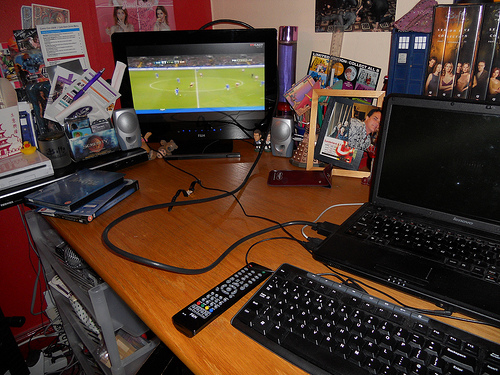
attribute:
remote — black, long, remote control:
[172, 262, 271, 338]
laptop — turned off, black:
[310, 93, 499, 324]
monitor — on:
[110, 26, 277, 145]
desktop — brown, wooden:
[39, 157, 230, 374]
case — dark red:
[267, 167, 333, 191]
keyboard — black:
[232, 263, 499, 375]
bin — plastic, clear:
[16, 214, 151, 374]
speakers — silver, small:
[270, 115, 294, 161]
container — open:
[1, 77, 23, 159]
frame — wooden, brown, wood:
[307, 84, 386, 176]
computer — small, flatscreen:
[112, 24, 277, 160]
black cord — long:
[101, 126, 336, 276]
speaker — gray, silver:
[112, 109, 143, 154]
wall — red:
[0, 1, 214, 29]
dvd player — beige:
[0, 152, 54, 191]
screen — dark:
[372, 98, 499, 226]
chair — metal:
[0, 309, 26, 374]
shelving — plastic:
[26, 216, 161, 374]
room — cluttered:
[0, 1, 499, 375]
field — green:
[128, 67, 264, 104]